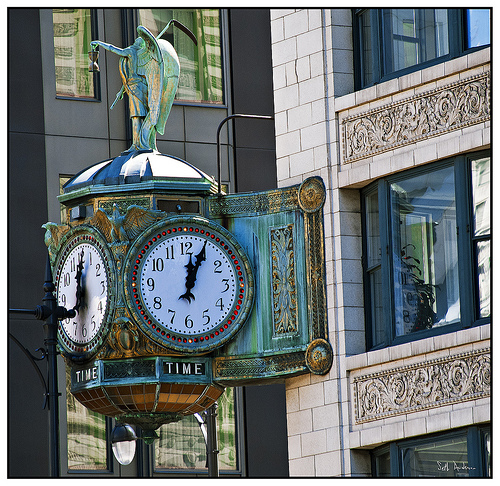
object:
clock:
[47, 228, 115, 363]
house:
[266, 11, 489, 474]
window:
[361, 161, 466, 350]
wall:
[275, 33, 323, 160]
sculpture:
[85, 19, 194, 156]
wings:
[139, 41, 164, 129]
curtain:
[377, 182, 402, 340]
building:
[0, 0, 500, 486]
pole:
[126, 420, 160, 483]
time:
[73, 367, 98, 383]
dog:
[234, 310, 239, 315]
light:
[107, 417, 137, 465]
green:
[231, 215, 268, 239]